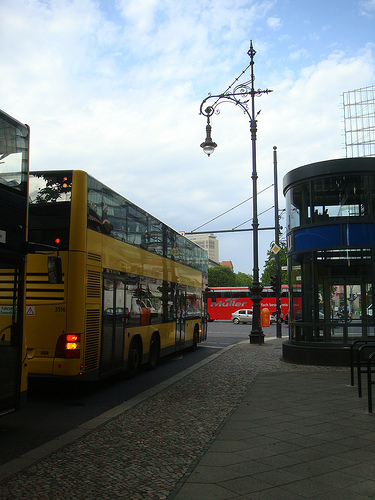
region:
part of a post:
[249, 189, 264, 217]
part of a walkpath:
[269, 398, 300, 444]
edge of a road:
[67, 429, 90, 440]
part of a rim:
[132, 342, 144, 376]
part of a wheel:
[128, 334, 144, 376]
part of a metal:
[354, 347, 365, 395]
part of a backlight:
[61, 336, 85, 353]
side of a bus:
[224, 283, 239, 321]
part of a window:
[326, 287, 351, 320]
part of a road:
[37, 400, 64, 421]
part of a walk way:
[264, 414, 299, 458]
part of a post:
[358, 372, 364, 398]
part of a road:
[40, 411, 72, 426]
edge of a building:
[271, 340, 307, 370]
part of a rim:
[132, 356, 139, 366]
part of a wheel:
[141, 336, 161, 372]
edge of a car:
[225, 303, 235, 320]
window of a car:
[235, 304, 248, 315]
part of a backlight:
[48, 320, 80, 360]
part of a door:
[104, 323, 123, 349]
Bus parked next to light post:
[1, 168, 219, 381]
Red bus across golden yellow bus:
[204, 283, 297, 324]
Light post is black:
[196, 38, 275, 343]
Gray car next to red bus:
[230, 304, 276, 324]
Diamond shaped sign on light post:
[271, 241, 280, 252]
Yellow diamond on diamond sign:
[272, 245, 277, 251]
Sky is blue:
[0, 0, 372, 283]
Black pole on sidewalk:
[348, 337, 355, 392]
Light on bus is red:
[65, 333, 76, 341]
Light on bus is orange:
[65, 341, 78, 349]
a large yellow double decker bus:
[3, 168, 214, 382]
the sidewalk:
[117, 355, 268, 496]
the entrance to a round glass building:
[321, 275, 364, 338]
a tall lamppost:
[196, 39, 272, 347]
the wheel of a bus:
[127, 331, 143, 378]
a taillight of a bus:
[64, 330, 79, 360]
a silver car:
[232, 306, 249, 323]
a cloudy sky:
[41, 4, 194, 164]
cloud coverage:
[60, 84, 184, 145]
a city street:
[216, 321, 243, 337]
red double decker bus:
[199, 269, 340, 352]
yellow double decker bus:
[6, 156, 249, 398]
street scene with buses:
[1, 167, 356, 480]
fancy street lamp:
[195, 71, 284, 378]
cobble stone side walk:
[32, 312, 328, 486]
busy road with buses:
[1, 105, 292, 417]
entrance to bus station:
[273, 130, 372, 408]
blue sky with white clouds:
[28, 14, 181, 135]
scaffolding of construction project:
[328, 75, 368, 149]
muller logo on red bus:
[223, 290, 255, 337]